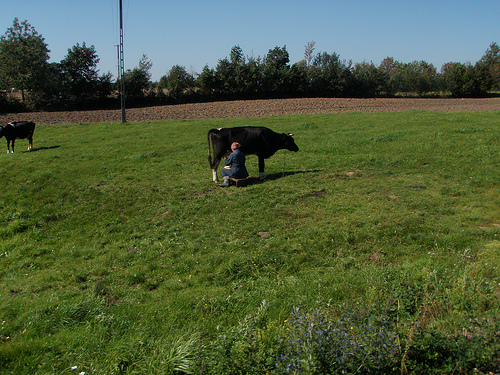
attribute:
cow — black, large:
[207, 126, 300, 180]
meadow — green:
[2, 110, 499, 374]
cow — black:
[2, 119, 37, 151]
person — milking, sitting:
[220, 139, 249, 188]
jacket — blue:
[225, 151, 247, 175]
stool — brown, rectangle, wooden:
[228, 175, 248, 188]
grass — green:
[4, 117, 484, 374]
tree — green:
[1, 17, 50, 105]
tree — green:
[62, 41, 100, 109]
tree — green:
[38, 60, 67, 112]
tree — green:
[97, 72, 117, 103]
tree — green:
[113, 54, 153, 103]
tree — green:
[157, 65, 193, 102]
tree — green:
[193, 65, 215, 95]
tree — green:
[216, 60, 236, 96]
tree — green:
[241, 62, 270, 98]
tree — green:
[261, 48, 291, 96]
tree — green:
[288, 58, 312, 98]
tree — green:
[310, 53, 349, 98]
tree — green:
[351, 61, 385, 99]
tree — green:
[377, 59, 408, 98]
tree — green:
[402, 58, 438, 97]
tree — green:
[433, 71, 448, 100]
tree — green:
[443, 61, 482, 99]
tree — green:
[474, 42, 500, 96]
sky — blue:
[3, 6, 498, 81]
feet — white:
[210, 169, 269, 183]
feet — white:
[4, 145, 34, 154]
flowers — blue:
[263, 289, 432, 373]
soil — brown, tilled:
[3, 94, 498, 113]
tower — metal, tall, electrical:
[115, 2, 128, 124]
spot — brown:
[256, 229, 271, 240]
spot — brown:
[346, 169, 354, 177]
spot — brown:
[388, 194, 398, 202]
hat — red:
[230, 140, 243, 152]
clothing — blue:
[220, 149, 248, 181]